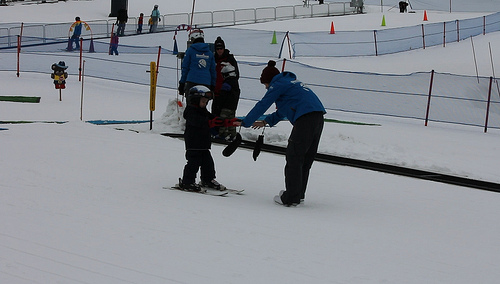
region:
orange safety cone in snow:
[323, 16, 341, 39]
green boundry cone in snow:
[375, 10, 389, 30]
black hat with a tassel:
[259, 54, 284, 93]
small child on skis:
[173, 78, 246, 200]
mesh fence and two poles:
[420, 66, 496, 136]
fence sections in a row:
[162, 1, 356, 31]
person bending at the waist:
[240, 56, 333, 213]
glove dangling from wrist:
[246, 113, 271, 171]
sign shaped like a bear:
[45, 56, 75, 104]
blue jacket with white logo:
[176, 41, 220, 88]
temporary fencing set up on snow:
[330, 11, 499, 139]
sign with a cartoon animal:
[41, 51, 76, 118]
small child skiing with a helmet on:
[161, 83, 250, 205]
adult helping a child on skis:
[163, 56, 330, 212]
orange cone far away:
[324, 15, 340, 39]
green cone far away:
[376, 10, 391, 32]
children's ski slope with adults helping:
[1, 1, 499, 281]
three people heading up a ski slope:
[26, 1, 374, 39]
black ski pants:
[281, 108, 328, 211]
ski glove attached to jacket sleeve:
[249, 115, 276, 165]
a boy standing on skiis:
[170, 78, 239, 207]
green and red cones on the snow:
[259, 7, 437, 44]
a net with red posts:
[13, 38, 498, 118]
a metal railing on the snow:
[3, 2, 353, 43]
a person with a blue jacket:
[233, 60, 328, 205]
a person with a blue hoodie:
[184, 24, 218, 91]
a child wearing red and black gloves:
[203, 117, 223, 127]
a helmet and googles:
[173, 76, 215, 110]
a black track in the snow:
[160, 120, 497, 198]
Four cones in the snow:
[270, 11, 430, 43]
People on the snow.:
[116, 15, 424, 227]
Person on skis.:
[152, 138, 319, 264]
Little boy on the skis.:
[163, 63, 289, 221]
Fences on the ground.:
[296, 23, 466, 165]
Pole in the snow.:
[128, 38, 168, 141]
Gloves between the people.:
[214, 98, 279, 169]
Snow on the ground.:
[38, 89, 185, 175]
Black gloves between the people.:
[218, 110, 308, 197]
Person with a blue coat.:
[236, 36, 351, 234]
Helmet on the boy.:
[183, 70, 223, 112]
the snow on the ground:
[0, 1, 497, 281]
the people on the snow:
[60, 0, 411, 207]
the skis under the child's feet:
[162, 174, 244, 195]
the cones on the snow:
[269, 11, 427, 45]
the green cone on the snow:
[269, 29, 279, 46]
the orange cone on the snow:
[328, 19, 336, 33]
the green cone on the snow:
[379, 14, 387, 26]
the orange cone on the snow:
[422, 9, 428, 21]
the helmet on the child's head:
[186, 84, 213, 100]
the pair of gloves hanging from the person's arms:
[222, 122, 266, 160]